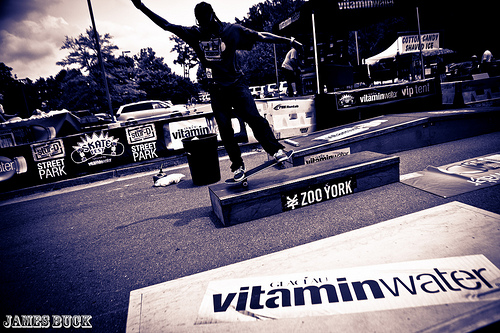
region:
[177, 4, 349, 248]
the man is skateboarding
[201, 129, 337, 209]
the player is wearing sneakers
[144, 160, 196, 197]
a dog is laying in the road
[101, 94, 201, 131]
car parked in the parking area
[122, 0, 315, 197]
a man standing is using skate board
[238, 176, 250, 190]
wheel of the skate board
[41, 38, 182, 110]
many trees with branches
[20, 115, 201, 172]
advertisement post on the road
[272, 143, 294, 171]
a man wearing white and black color shoe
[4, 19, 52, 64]
sky with the clouds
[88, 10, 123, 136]
post on the road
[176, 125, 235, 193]
dustbin in the road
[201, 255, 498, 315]
vitamin water advertisement on floor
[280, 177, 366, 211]
zoo york advertisement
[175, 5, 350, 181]
man on skateboard looking down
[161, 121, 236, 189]
black trash can bin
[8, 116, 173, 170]
various advertisements plastered on wall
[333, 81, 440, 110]
various advertisements plastered on wall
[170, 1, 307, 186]
man wearing a dark shirt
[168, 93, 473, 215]
man in skateboarding area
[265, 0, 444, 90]
black tent with people under it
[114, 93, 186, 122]
grey van parked in the back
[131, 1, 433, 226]
Man on a skateboard.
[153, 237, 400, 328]
Logo on the ground.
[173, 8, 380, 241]
Man on a skate ramp.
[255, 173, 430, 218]
Words on the skate ramp.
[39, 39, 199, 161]
Cars in the background.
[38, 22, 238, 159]
Trees in the background.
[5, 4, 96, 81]
White clouds in the sky.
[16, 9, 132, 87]
Clouds in the sky.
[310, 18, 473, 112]
Stands in the background.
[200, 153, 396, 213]
Skateboard under the skater.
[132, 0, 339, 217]
a person on a skateboard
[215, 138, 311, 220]
A skateboard on two wheels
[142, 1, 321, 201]
A person doing a trick on a skate board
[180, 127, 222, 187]
a garbage can in the street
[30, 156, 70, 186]
A banner with the words Street Park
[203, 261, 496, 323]
A sign that says Vitaminwater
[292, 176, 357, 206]
A sign that says Zoo York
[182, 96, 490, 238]
A place to skateboard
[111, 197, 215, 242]
the shadow of a man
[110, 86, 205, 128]
A van in a parking lot